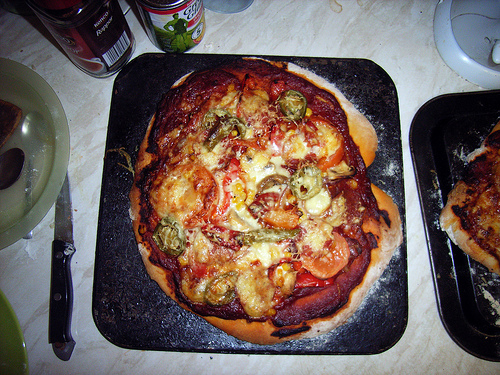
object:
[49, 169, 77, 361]
knife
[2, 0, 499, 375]
table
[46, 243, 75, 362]
handle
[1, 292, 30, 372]
plate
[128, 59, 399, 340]
pizza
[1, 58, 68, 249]
plate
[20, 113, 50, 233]
spoon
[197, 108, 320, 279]
middle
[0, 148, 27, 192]
spoon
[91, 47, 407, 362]
pan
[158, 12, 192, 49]
giant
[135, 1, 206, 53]
can